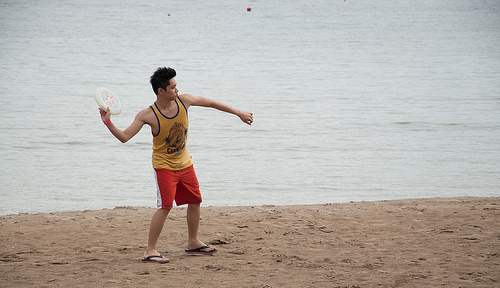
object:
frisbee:
[94, 86, 123, 115]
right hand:
[98, 106, 111, 123]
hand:
[239, 111, 253, 125]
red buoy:
[246, 7, 252, 11]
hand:
[97, 106, 110, 121]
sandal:
[142, 254, 171, 264]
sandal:
[185, 242, 218, 256]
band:
[104, 120, 112, 124]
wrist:
[103, 119, 112, 126]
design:
[151, 94, 193, 171]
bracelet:
[104, 120, 112, 125]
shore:
[261, 208, 468, 264]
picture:
[164, 121, 189, 154]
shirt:
[150, 95, 194, 170]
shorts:
[154, 165, 202, 210]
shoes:
[141, 242, 218, 264]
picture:
[0, 0, 500, 287]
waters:
[0, 0, 499, 215]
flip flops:
[141, 243, 217, 264]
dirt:
[0, 194, 499, 287]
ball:
[247, 7, 252, 11]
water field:
[139, 22, 482, 212]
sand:
[0, 193, 495, 284]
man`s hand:
[97, 107, 111, 125]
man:
[93, 66, 253, 263]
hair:
[149, 65, 177, 95]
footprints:
[0, 193, 499, 288]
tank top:
[150, 96, 193, 170]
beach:
[0, 192, 500, 288]